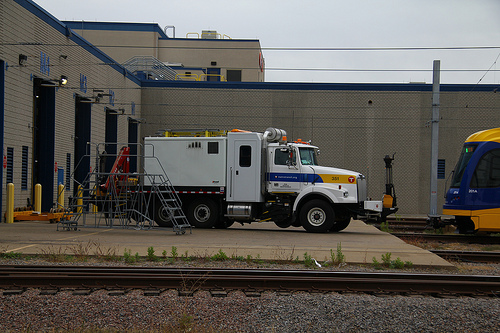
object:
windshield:
[299, 149, 317, 166]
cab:
[265, 136, 366, 206]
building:
[0, 0, 500, 226]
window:
[275, 148, 296, 165]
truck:
[87, 125, 399, 233]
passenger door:
[269, 146, 301, 189]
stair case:
[56, 142, 191, 234]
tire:
[299, 197, 337, 234]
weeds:
[12, 240, 418, 271]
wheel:
[184, 198, 222, 230]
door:
[233, 140, 258, 202]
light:
[59, 75, 69, 86]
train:
[442, 128, 499, 240]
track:
[428, 249, 500, 261]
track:
[372, 220, 485, 240]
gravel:
[0, 289, 500, 333]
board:
[179, 287, 193, 297]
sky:
[287, 0, 500, 43]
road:
[16, 219, 454, 266]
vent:
[21, 146, 29, 191]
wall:
[1, 0, 144, 212]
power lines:
[0, 42, 499, 72]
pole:
[5, 183, 14, 224]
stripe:
[269, 172, 356, 184]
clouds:
[261, 0, 500, 79]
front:
[437, 128, 484, 236]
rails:
[0, 264, 500, 294]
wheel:
[299, 199, 336, 233]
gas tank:
[225, 205, 252, 220]